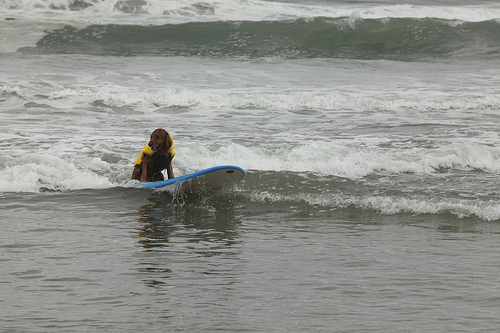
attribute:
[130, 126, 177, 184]
dog — brown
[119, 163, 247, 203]
surfboard — blue, white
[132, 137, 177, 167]
life jacket — yellow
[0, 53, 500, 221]
wave — small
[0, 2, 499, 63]
wave — small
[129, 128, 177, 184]
retriever — golden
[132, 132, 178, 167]
life jacket — yellow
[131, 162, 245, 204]
surfboard — blue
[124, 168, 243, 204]
botton — white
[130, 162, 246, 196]
board — blue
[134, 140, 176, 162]
life vest — yellow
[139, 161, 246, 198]
surfboard — blue and white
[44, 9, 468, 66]
wave — large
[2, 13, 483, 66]
ocean wave — white, green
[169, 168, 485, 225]
ocean wave — white, green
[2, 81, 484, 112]
ocean wave — white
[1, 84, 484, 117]
ocean wave — white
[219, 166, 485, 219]
ocean wave — green, white